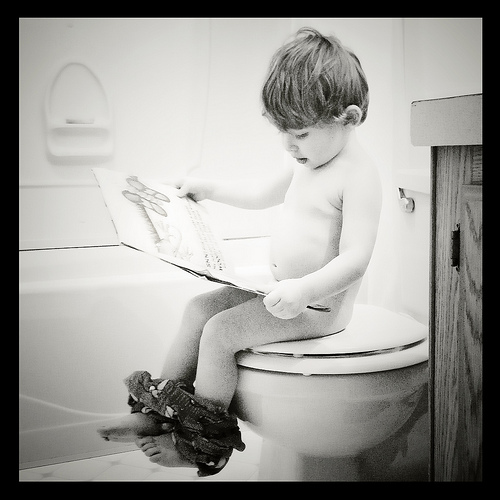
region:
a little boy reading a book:
[63, 44, 391, 304]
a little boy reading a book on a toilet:
[70, 59, 461, 423]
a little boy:
[186, 30, 380, 212]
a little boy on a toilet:
[183, 40, 455, 445]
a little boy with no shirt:
[195, 68, 388, 283]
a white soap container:
[38, 56, 140, 196]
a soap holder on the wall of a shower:
[26, 45, 148, 199]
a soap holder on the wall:
[23, 44, 145, 171]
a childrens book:
[73, 149, 284, 372]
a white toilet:
[269, 115, 495, 472]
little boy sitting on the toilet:
[91, 27, 439, 494]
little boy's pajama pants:
[113, 360, 243, 480]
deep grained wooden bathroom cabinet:
[416, 142, 487, 482]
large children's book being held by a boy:
[86, 153, 341, 318]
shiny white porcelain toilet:
[220, 164, 444, 484]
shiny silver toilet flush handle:
[394, 182, 419, 224]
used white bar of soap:
[60, 110, 94, 125]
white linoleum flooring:
[19, 418, 270, 485]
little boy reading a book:
[91, 24, 391, 481]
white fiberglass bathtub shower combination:
[13, 13, 408, 472]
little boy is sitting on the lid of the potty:
[96, 31, 378, 382]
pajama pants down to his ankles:
[89, 362, 234, 475]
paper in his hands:
[174, 259, 322, 325]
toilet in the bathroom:
[268, 345, 405, 475]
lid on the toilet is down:
[320, 342, 425, 356]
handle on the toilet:
[390, 185, 417, 218]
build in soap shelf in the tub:
[39, 55, 117, 175]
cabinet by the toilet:
[419, 281, 482, 456]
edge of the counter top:
[400, 82, 482, 137]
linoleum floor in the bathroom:
[47, 459, 164, 476]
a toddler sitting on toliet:
[77, 15, 405, 402]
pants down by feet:
[58, 348, 245, 490]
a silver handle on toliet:
[384, 180, 423, 214]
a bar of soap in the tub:
[5, 54, 129, 192]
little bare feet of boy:
[87, 405, 184, 483]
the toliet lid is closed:
[274, 302, 426, 397]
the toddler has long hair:
[243, 9, 376, 149]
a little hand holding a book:
[228, 260, 320, 322]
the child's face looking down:
[259, 113, 310, 180]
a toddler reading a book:
[35, 98, 382, 291]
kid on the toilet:
[98, 28, 382, 478]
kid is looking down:
[258, 29, 366, 169]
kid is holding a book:
[93, 163, 328, 316]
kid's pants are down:
[120, 370, 245, 475]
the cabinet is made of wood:
[430, 145, 485, 480]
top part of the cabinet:
[410, 95, 480, 145]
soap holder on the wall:
[42, 61, 108, 161]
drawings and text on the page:
[120, 172, 230, 267]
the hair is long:
[260, 28, 366, 128]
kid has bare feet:
[95, 409, 196, 464]